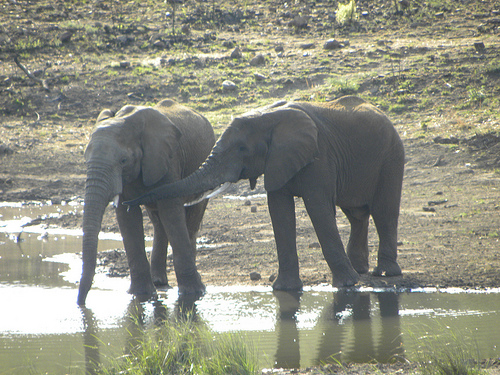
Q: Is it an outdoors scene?
A: Yes, it is outdoors.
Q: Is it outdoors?
A: Yes, it is outdoors.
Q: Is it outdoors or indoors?
A: It is outdoors.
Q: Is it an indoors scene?
A: No, it is outdoors.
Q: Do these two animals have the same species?
A: Yes, all the animals are elephants.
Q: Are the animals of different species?
A: No, all the animals are elephants.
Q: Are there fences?
A: No, there are no fences.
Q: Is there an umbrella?
A: No, there are no umbrellas.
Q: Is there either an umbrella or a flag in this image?
A: No, there are no umbrellas or flags.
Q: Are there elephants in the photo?
A: Yes, there is an elephant.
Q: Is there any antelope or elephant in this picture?
A: Yes, there is an elephant.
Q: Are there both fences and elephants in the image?
A: No, there is an elephant but no fences.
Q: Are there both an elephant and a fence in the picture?
A: No, there is an elephant but no fences.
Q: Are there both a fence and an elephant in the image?
A: No, there is an elephant but no fences.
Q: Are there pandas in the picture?
A: No, there are no pandas.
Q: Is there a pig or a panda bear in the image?
A: No, there are no pandas or pigs.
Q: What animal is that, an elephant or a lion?
A: That is an elephant.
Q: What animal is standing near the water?
A: The elephant is standing near the water.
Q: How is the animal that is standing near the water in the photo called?
A: The animal is an elephant.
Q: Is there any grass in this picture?
A: Yes, there is grass.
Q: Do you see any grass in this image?
A: Yes, there is grass.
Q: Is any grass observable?
A: Yes, there is grass.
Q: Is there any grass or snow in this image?
A: Yes, there is grass.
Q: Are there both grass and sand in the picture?
A: No, there is grass but no sand.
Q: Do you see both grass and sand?
A: No, there is grass but no sand.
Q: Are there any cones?
A: No, there are no cones.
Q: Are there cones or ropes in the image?
A: No, there are no cones or ropes.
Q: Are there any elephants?
A: Yes, there is an elephant.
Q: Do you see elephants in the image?
A: Yes, there is an elephant.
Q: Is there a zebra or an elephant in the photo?
A: Yes, there is an elephant.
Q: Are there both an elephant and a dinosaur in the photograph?
A: No, there is an elephant but no dinosaurs.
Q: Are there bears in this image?
A: No, there are no bears.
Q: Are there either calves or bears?
A: No, there are no bears or calves.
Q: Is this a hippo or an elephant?
A: This is an elephant.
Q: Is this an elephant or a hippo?
A: This is an elephant.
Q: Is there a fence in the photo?
A: No, there are no fences.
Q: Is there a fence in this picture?
A: No, there are no fences.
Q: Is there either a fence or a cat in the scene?
A: No, there are no fences or cats.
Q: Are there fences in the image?
A: No, there are no fences.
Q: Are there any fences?
A: No, there are no fences.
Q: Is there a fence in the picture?
A: No, there are no fences.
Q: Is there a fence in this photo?
A: No, there are no fences.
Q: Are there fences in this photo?
A: No, there are no fences.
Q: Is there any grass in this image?
A: Yes, there is grass.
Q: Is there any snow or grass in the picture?
A: Yes, there is grass.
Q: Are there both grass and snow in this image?
A: No, there is grass but no snow.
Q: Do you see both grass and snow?
A: No, there is grass but no snow.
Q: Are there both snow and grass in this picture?
A: No, there is grass but no snow.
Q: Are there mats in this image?
A: No, there are no mats.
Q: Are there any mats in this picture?
A: No, there are no mats.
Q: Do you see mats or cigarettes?
A: No, there are no mats or cigarettes.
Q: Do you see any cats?
A: No, there are no cats.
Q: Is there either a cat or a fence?
A: No, there are no cats or fences.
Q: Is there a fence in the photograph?
A: No, there are no fences.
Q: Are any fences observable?
A: No, there are no fences.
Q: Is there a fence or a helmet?
A: No, there are no fences or helmets.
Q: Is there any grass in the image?
A: Yes, there is grass.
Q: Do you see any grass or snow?
A: Yes, there is grass.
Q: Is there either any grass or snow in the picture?
A: Yes, there is grass.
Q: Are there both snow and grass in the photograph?
A: No, there is grass but no snow.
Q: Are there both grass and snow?
A: No, there is grass but no snow.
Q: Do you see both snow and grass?
A: No, there is grass but no snow.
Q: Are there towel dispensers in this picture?
A: No, there are no towel dispensers.